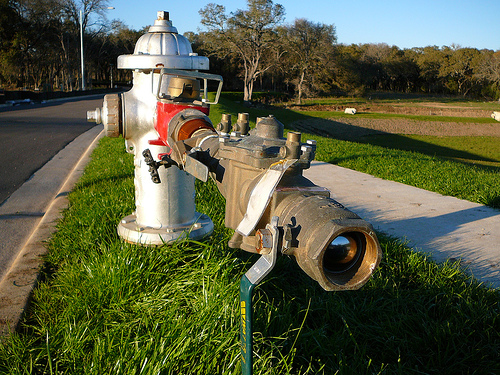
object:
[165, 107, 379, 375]
fire extinguisher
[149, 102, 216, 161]
hose attachment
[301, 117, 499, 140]
dirt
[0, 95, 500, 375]
grass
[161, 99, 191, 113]
tape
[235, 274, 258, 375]
handle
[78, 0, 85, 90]
lamp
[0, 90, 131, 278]
road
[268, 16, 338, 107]
trees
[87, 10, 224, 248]
hydrant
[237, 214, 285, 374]
lever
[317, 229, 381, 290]
opening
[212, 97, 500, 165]
shadow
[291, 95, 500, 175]
ground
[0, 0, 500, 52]
sky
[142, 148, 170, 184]
valve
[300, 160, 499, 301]
pavement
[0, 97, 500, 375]
field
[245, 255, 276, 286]
stake